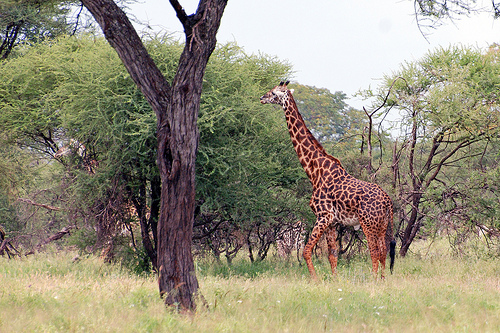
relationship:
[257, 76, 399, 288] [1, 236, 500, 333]
giraffe walking in field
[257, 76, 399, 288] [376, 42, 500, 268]
giraffe walking next to tree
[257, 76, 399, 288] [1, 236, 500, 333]
giraffe walking through field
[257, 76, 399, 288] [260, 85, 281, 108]
giraffe has face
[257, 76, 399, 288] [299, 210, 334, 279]
giraffe has leg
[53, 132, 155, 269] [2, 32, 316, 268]
giraffe behind tree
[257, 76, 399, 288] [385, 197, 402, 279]
giraffe has tail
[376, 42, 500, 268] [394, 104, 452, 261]
tree has trunk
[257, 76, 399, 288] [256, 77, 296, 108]
giraffe has head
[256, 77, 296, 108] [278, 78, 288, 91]
head has ossicones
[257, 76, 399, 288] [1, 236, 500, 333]
giraffe in field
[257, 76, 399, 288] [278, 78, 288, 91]
giraffe has ossicones